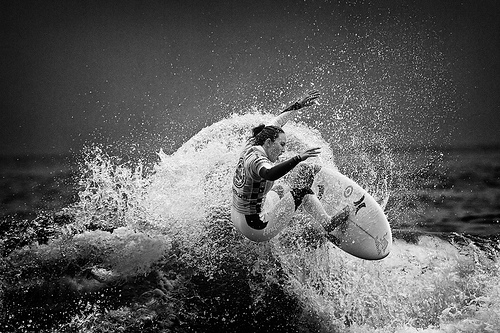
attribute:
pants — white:
[259, 185, 334, 245]